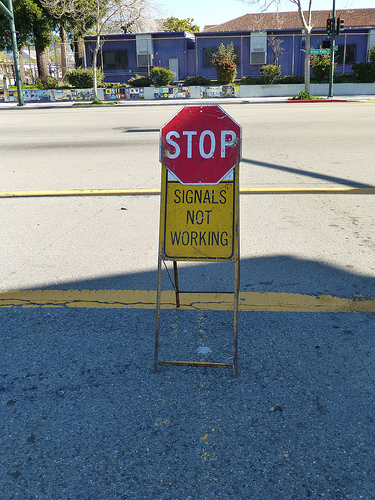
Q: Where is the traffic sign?
A: On the street.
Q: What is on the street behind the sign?
A: A yellow line.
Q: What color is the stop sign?
A: Red.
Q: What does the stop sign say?
A: Stop.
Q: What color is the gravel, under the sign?
A: The ground is grey.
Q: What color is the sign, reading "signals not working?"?
A: The sign is yellow.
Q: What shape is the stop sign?
A: The sign is an octagon.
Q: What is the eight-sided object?
A: A red and white stop sign.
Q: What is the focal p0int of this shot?
A: Two traffic signs on a metal stand.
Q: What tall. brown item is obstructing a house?
A: A tree, growing beside a roadway.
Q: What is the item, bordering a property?
A: A tall. metal fence.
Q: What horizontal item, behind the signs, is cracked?
A: A yellow line, painted on a road.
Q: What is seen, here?
A: Road signs in street.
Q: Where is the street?
A: Middle.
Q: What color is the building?
A: Blue.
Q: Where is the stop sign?
A: In the road.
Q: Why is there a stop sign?
A: Because the signals are not working.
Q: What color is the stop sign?
A: Red.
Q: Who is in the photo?
A: Nobody.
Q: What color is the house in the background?
A: Purple.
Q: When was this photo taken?
A: Daytime.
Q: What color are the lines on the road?
A: Yellow.